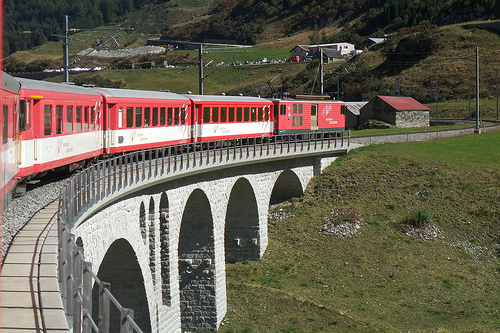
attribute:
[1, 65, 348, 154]
train — red, running, grey, white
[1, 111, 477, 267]
tracks — black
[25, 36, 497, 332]
grass — big, green, thick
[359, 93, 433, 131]
building — small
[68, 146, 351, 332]
bridge — white, grey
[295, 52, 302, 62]
barrel — Red,  metal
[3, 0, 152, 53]
trees —  pine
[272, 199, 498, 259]
landscape —  Rocky 